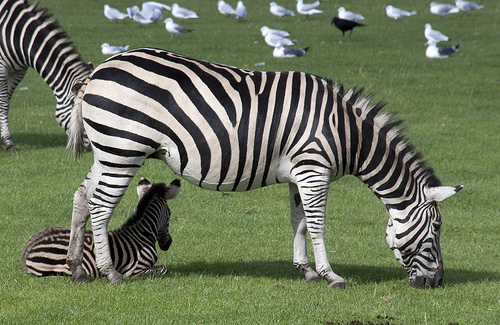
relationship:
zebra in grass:
[23, 176, 182, 280] [2, 5, 496, 323]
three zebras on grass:
[0, 0, 463, 289] [387, 64, 498, 114]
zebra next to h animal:
[23, 176, 182, 280] [67, 46, 465, 290]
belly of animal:
[149, 120, 289, 200] [67, 46, 465, 290]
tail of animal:
[66, 70, 91, 152] [67, 46, 465, 290]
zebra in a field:
[23, 176, 182, 280] [5, 0, 491, 319]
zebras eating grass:
[2, 1, 489, 316] [2, 5, 496, 323]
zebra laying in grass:
[23, 176, 182, 280] [2, 5, 496, 323]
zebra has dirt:
[23, 176, 182, 280] [25, 221, 91, 279]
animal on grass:
[67, 45, 460, 290] [2, 5, 496, 323]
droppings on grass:
[342, 310, 392, 320] [2, 5, 496, 323]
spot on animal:
[284, 184, 323, 285] [67, 46, 465, 290]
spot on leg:
[284, 184, 323, 285] [290, 165, 349, 295]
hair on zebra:
[349, 83, 445, 193] [86, 58, 455, 292]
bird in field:
[420, 38, 467, 60] [5, 0, 491, 319]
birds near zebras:
[93, 2, 499, 72] [2, 1, 489, 316]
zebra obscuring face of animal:
[1, 0, 91, 151] [67, 46, 465, 290]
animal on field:
[67, 46, 465, 290] [5, 0, 491, 319]